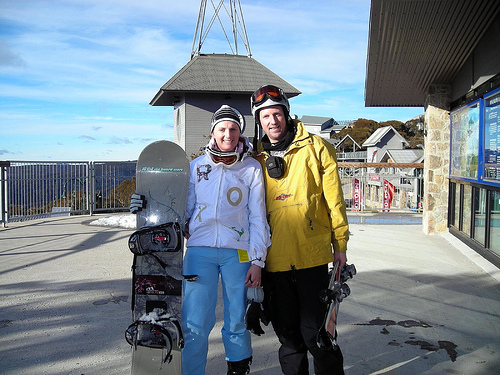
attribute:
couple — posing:
[179, 84, 355, 375]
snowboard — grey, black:
[124, 144, 194, 375]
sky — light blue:
[1, 0, 426, 159]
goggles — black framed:
[252, 85, 282, 103]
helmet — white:
[253, 88, 293, 121]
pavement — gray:
[1, 214, 500, 374]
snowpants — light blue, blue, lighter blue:
[185, 249, 253, 374]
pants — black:
[265, 267, 348, 375]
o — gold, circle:
[228, 180, 245, 206]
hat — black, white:
[213, 105, 242, 135]